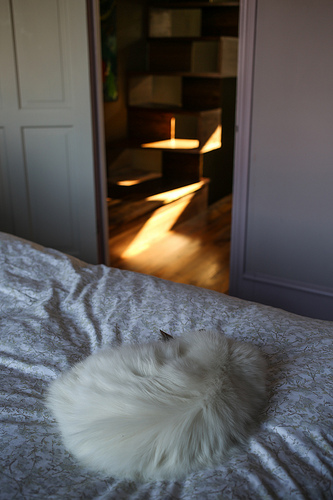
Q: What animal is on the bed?
A: A cat.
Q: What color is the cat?
A: White.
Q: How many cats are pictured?
A: One.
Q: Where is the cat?
A: On the bed.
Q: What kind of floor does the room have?
A: Wood.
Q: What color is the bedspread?
A: White with a pattern.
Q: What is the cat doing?
A: Sleeping.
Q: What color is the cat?
A: White.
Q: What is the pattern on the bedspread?
A: Floral.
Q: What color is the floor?
A: Brown.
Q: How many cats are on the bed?
A: One.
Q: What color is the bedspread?
A: White.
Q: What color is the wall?
A: White.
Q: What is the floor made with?
A: Wood.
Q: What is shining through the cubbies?
A: Sunlight.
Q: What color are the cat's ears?
A: Black.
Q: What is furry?
A: The cat.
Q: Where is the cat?
A: On bed.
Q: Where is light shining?
A: On floor.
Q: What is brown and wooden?
A: The floor.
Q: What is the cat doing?
A: Sleeping.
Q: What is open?
A: Door.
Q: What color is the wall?
A: White.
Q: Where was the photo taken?
A: In a bedroom.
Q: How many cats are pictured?
A: One.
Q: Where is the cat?
A: On a bed.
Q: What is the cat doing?
A: Sleeping.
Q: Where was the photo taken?
A: In a bedroom.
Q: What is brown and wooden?
A: The floor.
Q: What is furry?
A: The cat.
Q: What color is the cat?
A: White.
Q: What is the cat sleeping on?
A: The bed.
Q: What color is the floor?
A: Brown.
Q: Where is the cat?
A: On the bed.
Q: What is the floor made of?
A: Wood.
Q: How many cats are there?
A: One.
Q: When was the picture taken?
A: Daytime.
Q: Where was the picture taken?
A: A bedroom.